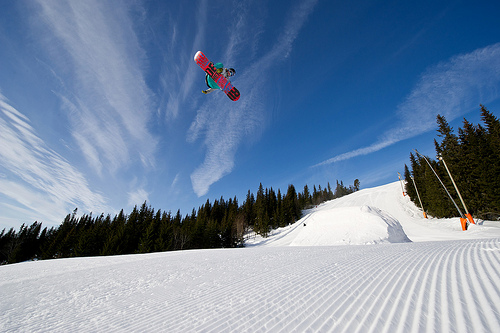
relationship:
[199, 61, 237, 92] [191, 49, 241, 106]
man on snowboard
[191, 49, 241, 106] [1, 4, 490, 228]
snowboard in sky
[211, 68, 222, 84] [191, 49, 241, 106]
letters on snowboard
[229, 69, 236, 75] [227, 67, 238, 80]
googles on face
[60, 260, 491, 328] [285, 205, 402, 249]
snow on ramp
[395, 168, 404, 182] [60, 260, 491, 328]
flag on snow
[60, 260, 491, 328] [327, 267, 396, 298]
snow has lines